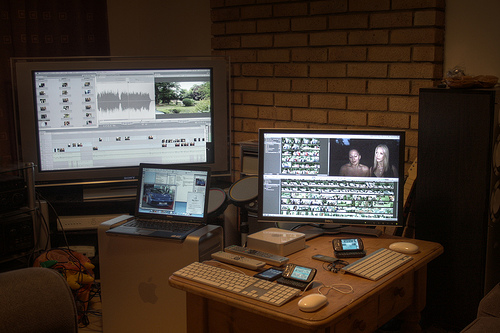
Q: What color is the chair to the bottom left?
A: Grey.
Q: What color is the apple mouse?
A: White.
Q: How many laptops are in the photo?
A: One.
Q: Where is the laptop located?
A: On top of the computer tower.